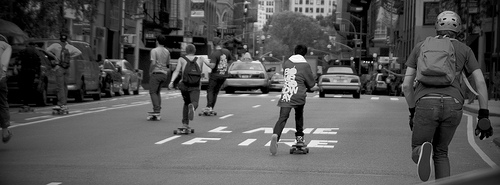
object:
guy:
[401, 11, 494, 184]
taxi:
[225, 53, 271, 93]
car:
[319, 66, 363, 99]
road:
[1, 94, 499, 183]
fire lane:
[154, 126, 340, 149]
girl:
[167, 43, 207, 127]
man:
[47, 30, 84, 107]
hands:
[55, 59, 60, 64]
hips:
[50, 66, 70, 78]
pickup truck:
[11, 39, 103, 106]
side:
[0, 12, 90, 114]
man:
[268, 43, 318, 155]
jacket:
[277, 65, 315, 107]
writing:
[282, 87, 297, 98]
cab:
[227, 60, 247, 79]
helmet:
[432, 10, 461, 33]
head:
[435, 11, 462, 36]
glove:
[399, 107, 419, 130]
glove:
[473, 109, 494, 141]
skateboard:
[173, 126, 194, 134]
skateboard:
[197, 108, 217, 116]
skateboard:
[147, 110, 163, 121]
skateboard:
[54, 104, 70, 115]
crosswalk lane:
[173, 91, 400, 101]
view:
[15, 13, 482, 156]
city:
[0, 0, 499, 185]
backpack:
[415, 36, 455, 89]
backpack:
[178, 56, 205, 87]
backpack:
[55, 43, 75, 68]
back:
[392, 36, 484, 101]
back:
[177, 57, 207, 87]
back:
[42, 42, 77, 67]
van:
[97, 58, 146, 97]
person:
[200, 36, 235, 110]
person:
[148, 36, 172, 115]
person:
[0, 32, 14, 144]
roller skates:
[287, 135, 309, 156]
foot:
[291, 135, 309, 148]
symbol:
[285, 66, 299, 74]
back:
[275, 54, 321, 106]